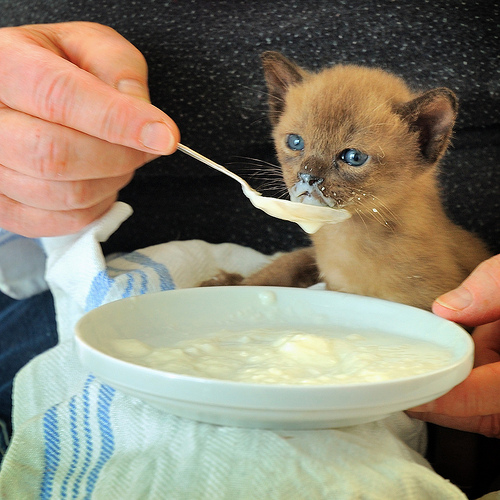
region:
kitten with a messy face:
[247, 42, 455, 230]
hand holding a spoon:
[5, 36, 341, 243]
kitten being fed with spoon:
[232, 5, 442, 243]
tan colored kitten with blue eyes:
[255, 47, 466, 283]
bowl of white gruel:
[78, 284, 474, 426]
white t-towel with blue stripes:
[3, 402, 153, 497]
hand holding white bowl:
[87, 241, 499, 437]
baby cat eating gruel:
[239, 44, 435, 427]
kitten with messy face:
[255, 46, 444, 216]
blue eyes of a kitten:
[276, 125, 374, 170]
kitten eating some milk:
[223, 44, 469, 231]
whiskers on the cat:
[316, 176, 390, 218]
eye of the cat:
[333, 130, 383, 187]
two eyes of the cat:
[261, 105, 387, 191]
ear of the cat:
[401, 79, 471, 141]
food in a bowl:
[216, 318, 334, 391]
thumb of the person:
[425, 258, 495, 331]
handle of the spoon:
[177, 142, 247, 199]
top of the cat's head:
[301, 71, 386, 137]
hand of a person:
[1, 20, 184, 249]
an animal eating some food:
[73, 84, 468, 419]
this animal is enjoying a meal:
[244, 61, 474, 291]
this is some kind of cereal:
[90, 269, 477, 426]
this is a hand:
[19, 35, 174, 237]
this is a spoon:
[178, 117, 349, 237]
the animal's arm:
[200, 232, 346, 291]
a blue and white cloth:
[50, 231, 141, 496]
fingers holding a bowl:
[426, 249, 498, 413]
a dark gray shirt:
[145, 24, 495, 246]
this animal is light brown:
[255, 61, 441, 282]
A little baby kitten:
[6, 10, 476, 445]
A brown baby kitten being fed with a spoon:
[220, 53, 467, 237]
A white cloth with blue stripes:
[72, 391, 249, 492]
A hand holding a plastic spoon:
[28, 53, 255, 236]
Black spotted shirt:
[183, 20, 267, 140]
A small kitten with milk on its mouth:
[273, 167, 361, 230]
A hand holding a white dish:
[414, 275, 495, 415]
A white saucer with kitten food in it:
[127, 313, 361, 405]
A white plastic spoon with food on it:
[183, 146, 353, 245]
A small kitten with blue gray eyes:
[259, 107, 391, 219]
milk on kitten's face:
[286, 174, 338, 211]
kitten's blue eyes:
[283, 128, 371, 168]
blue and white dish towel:
[4, 196, 466, 497]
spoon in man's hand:
[175, 135, 352, 237]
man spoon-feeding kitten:
[1, 0, 493, 446]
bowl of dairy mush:
[71, 280, 472, 431]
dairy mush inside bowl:
[114, 320, 456, 387]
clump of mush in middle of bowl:
[273, 328, 344, 365]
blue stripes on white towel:
[37, 242, 177, 497]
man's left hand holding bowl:
[403, 236, 498, 437]